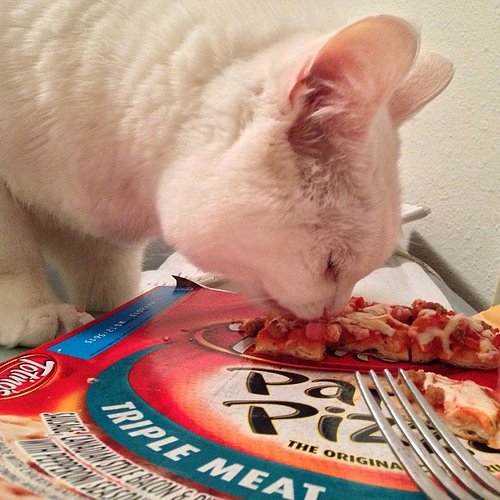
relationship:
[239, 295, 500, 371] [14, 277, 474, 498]
pizza on box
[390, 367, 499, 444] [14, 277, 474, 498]
pizza on box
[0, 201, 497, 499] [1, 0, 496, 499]
box on table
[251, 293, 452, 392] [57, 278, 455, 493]
slice on box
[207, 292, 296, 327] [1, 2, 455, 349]
whiskers on cat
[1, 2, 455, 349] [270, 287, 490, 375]
cat enjoying pizza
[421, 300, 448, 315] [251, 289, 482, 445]
meatball on pizza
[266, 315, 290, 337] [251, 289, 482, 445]
meatball on pizza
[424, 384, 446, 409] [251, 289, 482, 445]
meatball on pizza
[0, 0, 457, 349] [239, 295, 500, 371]
cat eating pizza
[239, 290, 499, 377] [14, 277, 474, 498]
pizza on box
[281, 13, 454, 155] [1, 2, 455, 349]
ears of cat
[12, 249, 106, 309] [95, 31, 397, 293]
legs of cat